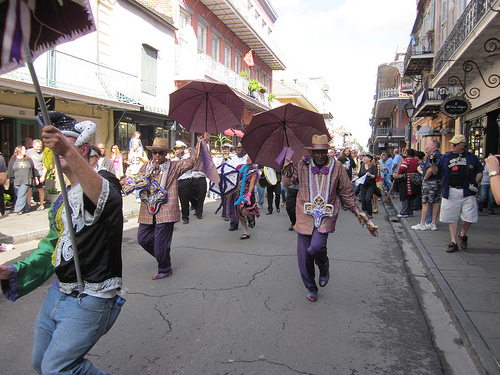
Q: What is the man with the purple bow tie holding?
A: Umbrella.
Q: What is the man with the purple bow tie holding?
A: Umbrella.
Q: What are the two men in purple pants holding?
A: Umbrellas.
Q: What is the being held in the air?
A: Umbrella.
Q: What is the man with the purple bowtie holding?
A: An Umbrella.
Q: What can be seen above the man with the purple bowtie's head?
A: Umbrella.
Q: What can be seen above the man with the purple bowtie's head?
A: Umbrella.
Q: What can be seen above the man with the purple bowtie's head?
A: Umbrella.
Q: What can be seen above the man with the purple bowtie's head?
A: Umbrella.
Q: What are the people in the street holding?
A: Umbrellas.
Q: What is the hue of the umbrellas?
A: Brown and black.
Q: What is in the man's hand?
A: Umbrella.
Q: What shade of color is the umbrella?
A: Purple.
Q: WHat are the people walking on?
A: Road.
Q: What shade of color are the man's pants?
A: Purple.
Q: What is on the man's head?
A: Hat.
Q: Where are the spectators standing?
A: Sidewalks.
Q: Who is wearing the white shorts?
A: The man on the right sidewalk.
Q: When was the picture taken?
A: In the daytime.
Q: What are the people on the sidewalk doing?
A: Watching.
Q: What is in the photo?
A: A parade.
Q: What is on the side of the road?
A: A curb.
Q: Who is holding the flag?
A: A man.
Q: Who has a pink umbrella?
A: A man.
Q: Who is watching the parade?
A: People on the sidewalk.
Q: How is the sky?
A: Clear and blue.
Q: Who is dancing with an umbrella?
A: A man.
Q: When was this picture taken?
A: Late morning.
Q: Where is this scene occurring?
A: New Orleans.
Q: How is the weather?
A: Sunny and warm.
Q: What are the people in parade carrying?
A: Umbrellas.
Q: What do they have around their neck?
A: Oversized necklaces.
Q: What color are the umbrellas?
A: Pink.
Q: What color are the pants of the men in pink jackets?
A: Purple.